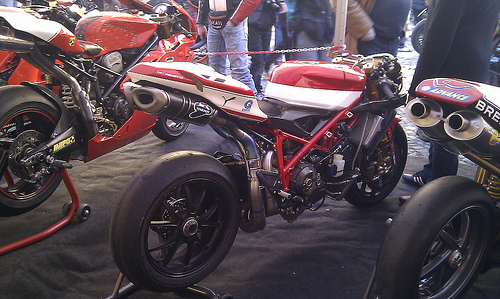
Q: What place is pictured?
A: It is a display.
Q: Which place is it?
A: It is a display.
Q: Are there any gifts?
A: No, there are no gifts.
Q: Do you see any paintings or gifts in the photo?
A: No, there are no gifts or paintings.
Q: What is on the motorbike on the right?
A: The pipes are on the motorbike.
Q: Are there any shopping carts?
A: No, there are no shopping carts.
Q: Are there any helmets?
A: No, there are no helmets.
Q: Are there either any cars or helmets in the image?
A: No, there are no helmets or cars.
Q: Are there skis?
A: No, there are no skis.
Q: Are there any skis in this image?
A: No, there are no skis.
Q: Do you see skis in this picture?
A: No, there are no skis.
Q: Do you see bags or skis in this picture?
A: No, there are no skis or bags.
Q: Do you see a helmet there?
A: No, there are no helmets.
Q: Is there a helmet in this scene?
A: No, there are no helmets.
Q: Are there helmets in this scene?
A: No, there are no helmets.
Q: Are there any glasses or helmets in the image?
A: No, there are no helmets or glasses.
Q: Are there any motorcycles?
A: Yes, there is a motorcycle.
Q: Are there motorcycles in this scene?
A: Yes, there is a motorcycle.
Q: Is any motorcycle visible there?
A: Yes, there is a motorcycle.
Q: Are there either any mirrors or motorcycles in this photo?
A: Yes, there is a motorcycle.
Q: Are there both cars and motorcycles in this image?
A: No, there is a motorcycle but no cars.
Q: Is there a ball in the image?
A: No, there are no balls.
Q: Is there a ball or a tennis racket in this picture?
A: No, there are no balls or rackets.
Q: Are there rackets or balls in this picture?
A: No, there are no balls or rackets.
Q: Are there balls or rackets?
A: No, there are no balls or rackets.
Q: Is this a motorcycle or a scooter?
A: This is a motorcycle.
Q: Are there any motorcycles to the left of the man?
A: Yes, there is a motorcycle to the left of the man.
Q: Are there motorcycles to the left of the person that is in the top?
A: Yes, there is a motorcycle to the left of the man.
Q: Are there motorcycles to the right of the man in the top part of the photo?
A: No, the motorcycle is to the left of the man.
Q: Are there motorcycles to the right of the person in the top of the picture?
A: No, the motorcycle is to the left of the man.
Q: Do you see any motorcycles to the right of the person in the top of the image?
A: No, the motorcycle is to the left of the man.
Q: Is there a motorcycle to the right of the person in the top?
A: No, the motorcycle is to the left of the man.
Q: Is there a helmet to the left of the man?
A: No, there is a motorcycle to the left of the man.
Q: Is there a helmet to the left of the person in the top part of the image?
A: No, there is a motorcycle to the left of the man.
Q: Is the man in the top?
A: Yes, the man is in the top of the image.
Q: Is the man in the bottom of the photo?
A: No, the man is in the top of the image.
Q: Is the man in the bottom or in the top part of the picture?
A: The man is in the top of the image.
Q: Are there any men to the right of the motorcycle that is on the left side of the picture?
A: Yes, there is a man to the right of the motorbike.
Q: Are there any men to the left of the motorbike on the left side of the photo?
A: No, the man is to the right of the motorcycle.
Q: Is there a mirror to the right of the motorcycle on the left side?
A: No, there is a man to the right of the motorbike.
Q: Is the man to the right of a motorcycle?
A: Yes, the man is to the right of a motorcycle.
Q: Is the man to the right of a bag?
A: No, the man is to the right of a motorcycle.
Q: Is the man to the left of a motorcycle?
A: No, the man is to the right of a motorcycle.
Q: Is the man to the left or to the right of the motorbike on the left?
A: The man is to the right of the motorcycle.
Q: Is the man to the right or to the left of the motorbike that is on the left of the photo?
A: The man is to the right of the motorcycle.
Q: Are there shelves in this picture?
A: No, there are no shelves.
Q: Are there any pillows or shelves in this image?
A: No, there are no shelves or pillows.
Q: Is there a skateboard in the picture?
A: No, there are no skateboards.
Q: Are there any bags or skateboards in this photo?
A: No, there are no skateboards or bags.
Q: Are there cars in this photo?
A: No, there are no cars.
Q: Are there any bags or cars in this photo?
A: No, there are no cars or bags.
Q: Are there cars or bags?
A: No, there are no cars or bags.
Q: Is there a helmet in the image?
A: No, there are no helmets.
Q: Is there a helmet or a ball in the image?
A: No, there are no helmets or balls.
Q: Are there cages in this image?
A: No, there are no cages.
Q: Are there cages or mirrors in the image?
A: No, there are no cages or mirrors.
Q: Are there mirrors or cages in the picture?
A: No, there are no cages or mirrors.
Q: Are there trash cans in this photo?
A: No, there are no trash cans.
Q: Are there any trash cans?
A: No, there are no trash cans.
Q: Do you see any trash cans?
A: No, there are no trash cans.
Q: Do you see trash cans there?
A: No, there are no trash cans.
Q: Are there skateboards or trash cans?
A: No, there are no trash cans or skateboards.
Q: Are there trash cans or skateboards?
A: No, there are no trash cans or skateboards.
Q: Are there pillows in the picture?
A: No, there are no pillows.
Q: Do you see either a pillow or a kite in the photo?
A: No, there are no pillows or kites.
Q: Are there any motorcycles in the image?
A: Yes, there is a motorcycle.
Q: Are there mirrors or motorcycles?
A: Yes, there is a motorcycle.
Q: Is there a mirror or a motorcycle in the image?
A: Yes, there is a motorcycle.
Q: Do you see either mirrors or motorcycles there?
A: Yes, there is a motorcycle.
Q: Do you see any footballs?
A: No, there are no footballs.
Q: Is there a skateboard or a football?
A: No, there are no footballs or skateboards.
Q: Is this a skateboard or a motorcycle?
A: This is a motorcycle.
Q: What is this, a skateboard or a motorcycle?
A: This is a motorcycle.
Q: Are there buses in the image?
A: No, there are no buses.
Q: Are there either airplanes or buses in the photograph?
A: No, there are no buses or airplanes.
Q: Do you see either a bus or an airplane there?
A: No, there are no buses or airplanes.